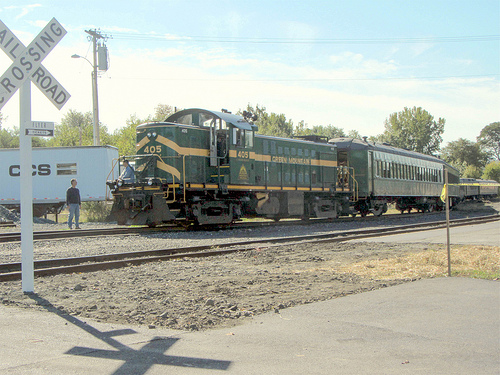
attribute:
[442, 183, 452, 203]
flag — yellow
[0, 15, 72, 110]
sign — white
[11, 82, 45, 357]
pole — white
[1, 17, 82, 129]
sign — railroad crossing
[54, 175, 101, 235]
person — standing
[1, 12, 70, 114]
sign — white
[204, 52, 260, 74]
clouds — white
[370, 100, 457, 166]
bush — green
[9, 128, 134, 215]
trailer — white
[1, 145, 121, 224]
trailer car — white